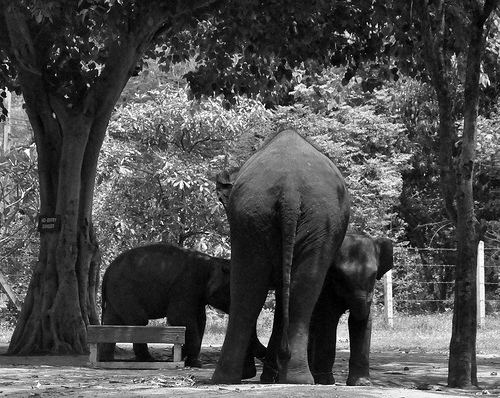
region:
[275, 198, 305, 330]
A tail of an elephant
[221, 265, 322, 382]
Legs of an elephant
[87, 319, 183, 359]
A wooden bar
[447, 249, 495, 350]
A tree trunk in the photo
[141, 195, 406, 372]
Elephants in the picture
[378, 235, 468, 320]
Barbed wire fence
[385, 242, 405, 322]
A pole at the back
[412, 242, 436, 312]
A fence in the photo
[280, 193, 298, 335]
A tail hanging down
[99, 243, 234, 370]
The elephant is young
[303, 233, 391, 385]
Young elephant is walking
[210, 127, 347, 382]
Elephant is an adult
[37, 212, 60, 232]
Sign on the tree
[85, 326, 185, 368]
A little wood post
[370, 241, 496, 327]
A small metal fence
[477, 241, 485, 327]
Fence post is white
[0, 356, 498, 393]
Dirt on the ground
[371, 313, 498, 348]
There is some overgrown grass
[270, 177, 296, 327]
The tail of the elephant in the middle.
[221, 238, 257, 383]
The back left leg of the elephant in the middle.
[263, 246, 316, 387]
The back right leg of the elephant in the middle.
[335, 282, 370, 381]
The trunk of the elephant on the right.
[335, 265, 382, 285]
The eyes of the elephant on the right.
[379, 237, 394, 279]
The ear of the elephant on the right.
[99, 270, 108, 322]
The tail of the elephant on the left.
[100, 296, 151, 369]
The back legs of the elephant on the left.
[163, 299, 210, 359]
The front legs of the elephant on the left.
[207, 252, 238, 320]
The back of the head of the elephant on the left.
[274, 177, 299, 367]
tail of an elephant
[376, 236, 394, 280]
ear of an elephant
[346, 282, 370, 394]
trunk of an elephant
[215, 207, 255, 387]
rear leg of an elephant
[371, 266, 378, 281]
eye of an elephant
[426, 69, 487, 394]
trunk of a tree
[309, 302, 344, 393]
front leg of an elephant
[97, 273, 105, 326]
tail of an elephant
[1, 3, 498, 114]
leaves hanging on trees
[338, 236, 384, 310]
head of an elephant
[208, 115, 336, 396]
A large elephant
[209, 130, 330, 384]
A large elephants rump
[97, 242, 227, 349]
A little baby elephant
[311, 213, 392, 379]
A young elephant next to large elephant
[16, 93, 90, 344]
A large tree trunk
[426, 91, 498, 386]
A small tree trunk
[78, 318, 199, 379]
A wooden bench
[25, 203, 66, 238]
A sign on the tree trunk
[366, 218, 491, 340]
A fence with square post